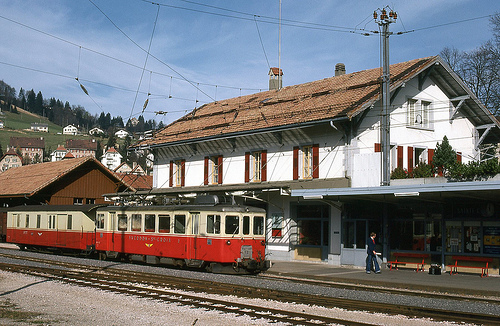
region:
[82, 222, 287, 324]
Bottom of train is red.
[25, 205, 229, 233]
Mid section of train is white.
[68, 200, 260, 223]
Roof of train is black.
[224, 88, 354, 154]
Roof on building is brown.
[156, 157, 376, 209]
Building has brown shutters on building.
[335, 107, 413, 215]
Building next to train is white.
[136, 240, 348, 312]
Gravel next to train.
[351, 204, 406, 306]
Person walking on sidewalk near train.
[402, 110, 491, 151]
Green plants on roof top near train.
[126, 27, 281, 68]
Sky is blue with white clouds.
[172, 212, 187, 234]
a window on the train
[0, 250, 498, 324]
a pair of train tracks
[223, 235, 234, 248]
a headlight on the train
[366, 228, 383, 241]
the head of a man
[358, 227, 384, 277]
a man on the sidewalk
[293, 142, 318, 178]
a window on the building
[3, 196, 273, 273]
a red and white train on the tracks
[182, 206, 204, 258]
the door of a train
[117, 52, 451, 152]
a brown building roof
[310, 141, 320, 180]
a red window shutter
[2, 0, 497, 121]
The sky is blue.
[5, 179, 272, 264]
The train is red and white.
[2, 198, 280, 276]
The train is on the tracks.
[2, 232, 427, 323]
The tracks are brown.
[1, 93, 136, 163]
the grass is green.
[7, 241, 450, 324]
Gravel between the tracks.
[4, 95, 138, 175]
Houses on the hills.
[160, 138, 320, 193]
The shutters are red.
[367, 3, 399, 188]
The pole is wooden.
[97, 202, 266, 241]
Windows on the train.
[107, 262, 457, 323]
train rails in background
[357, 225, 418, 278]
man waiting for train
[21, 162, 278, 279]
big red train in picture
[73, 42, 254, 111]
electrical wires in the sky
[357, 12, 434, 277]
telephone pole in background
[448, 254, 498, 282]
orange bent in background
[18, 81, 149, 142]
green trees in the background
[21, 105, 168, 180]
homes in the background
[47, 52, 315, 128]
clear blue sky in background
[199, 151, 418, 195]
red windows on the tree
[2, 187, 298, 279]
Local train stopped station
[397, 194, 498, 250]
Convenience store next station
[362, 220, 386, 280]
Person walking slowly sidewalk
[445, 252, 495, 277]
Red wooden bench seating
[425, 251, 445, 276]
Trash recepticle between benchs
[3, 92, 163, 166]
Many house buildings hillside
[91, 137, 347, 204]
Electric wiring needed train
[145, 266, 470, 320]
Gravel bed between train tracks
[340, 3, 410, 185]
Electrical utility pole carries lines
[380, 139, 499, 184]
Outdoor cafe surrounded foliage